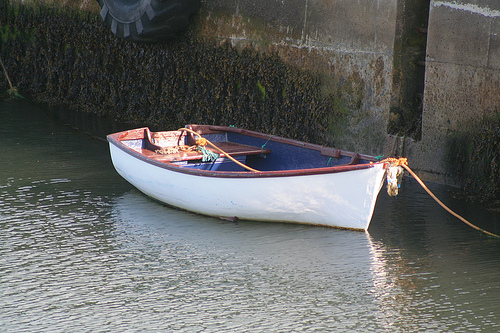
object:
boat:
[106, 123, 393, 232]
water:
[0, 99, 498, 332]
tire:
[95, 0, 201, 42]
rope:
[177, 126, 265, 175]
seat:
[130, 140, 269, 164]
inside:
[123, 132, 375, 173]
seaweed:
[286, 76, 308, 137]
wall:
[1, 3, 497, 198]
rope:
[175, 127, 499, 240]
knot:
[197, 136, 206, 147]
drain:
[386, 1, 433, 143]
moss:
[475, 224, 499, 240]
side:
[109, 144, 388, 232]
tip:
[363, 152, 393, 232]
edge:
[106, 124, 389, 178]